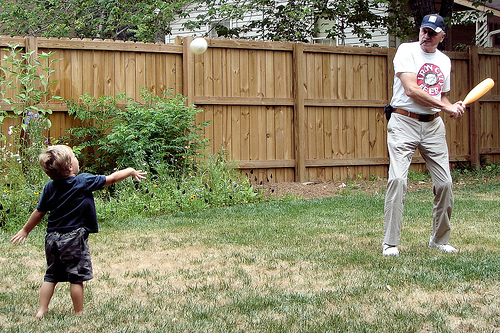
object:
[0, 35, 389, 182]
fence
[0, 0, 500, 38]
trees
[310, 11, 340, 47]
window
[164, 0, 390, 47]
house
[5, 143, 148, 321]
child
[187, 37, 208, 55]
ball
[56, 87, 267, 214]
bushes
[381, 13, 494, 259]
man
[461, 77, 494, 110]
bat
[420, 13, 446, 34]
hat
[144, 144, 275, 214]
flowers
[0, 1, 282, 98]
air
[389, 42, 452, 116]
white shirt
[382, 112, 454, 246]
pants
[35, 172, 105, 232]
shirt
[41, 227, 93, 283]
shorts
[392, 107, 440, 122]
belt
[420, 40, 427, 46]
cigar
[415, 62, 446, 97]
logo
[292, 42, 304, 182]
post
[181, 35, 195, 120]
post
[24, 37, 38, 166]
post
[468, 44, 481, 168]
post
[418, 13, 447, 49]
head